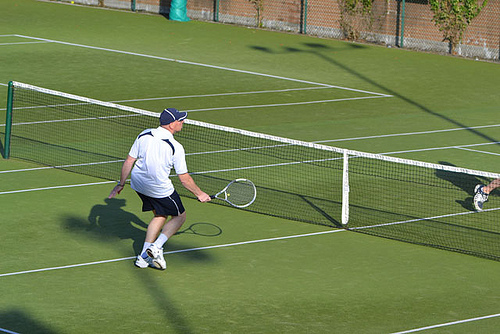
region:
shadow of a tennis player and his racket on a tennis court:
[87, 196, 222, 265]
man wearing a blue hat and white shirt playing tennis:
[106, 107, 213, 269]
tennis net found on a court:
[4, 78, 499, 258]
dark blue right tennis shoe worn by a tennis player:
[473, 183, 488, 211]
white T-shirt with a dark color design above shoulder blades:
[128, 125, 188, 198]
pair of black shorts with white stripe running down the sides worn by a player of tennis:
[136, 189, 186, 216]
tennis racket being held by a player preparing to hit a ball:
[208, 175, 256, 207]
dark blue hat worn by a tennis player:
[160, 106, 186, 128]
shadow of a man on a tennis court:
[89, 196, 150, 256]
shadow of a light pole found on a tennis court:
[249, 43, 499, 146]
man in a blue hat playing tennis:
[5, 6, 497, 326]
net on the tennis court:
[0, 77, 115, 177]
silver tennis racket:
[210, 170, 255, 210]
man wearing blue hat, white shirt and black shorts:
[106, 105, 258, 269]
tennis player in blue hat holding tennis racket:
[106, 92, 255, 269]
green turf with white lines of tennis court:
[254, 52, 467, 123]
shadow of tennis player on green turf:
[80, 197, 140, 249]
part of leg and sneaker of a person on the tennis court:
[467, 169, 497, 221]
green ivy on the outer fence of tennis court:
[419, 2, 487, 54]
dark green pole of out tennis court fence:
[390, 0, 410, 48]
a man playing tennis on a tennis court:
[109, 107, 256, 271]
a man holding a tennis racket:
[198, 175, 257, 207]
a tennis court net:
[4, 80, 499, 267]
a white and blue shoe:
[473, 183, 490, 215]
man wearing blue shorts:
[136, 188, 183, 215]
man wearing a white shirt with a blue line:
[130, 124, 188, 196]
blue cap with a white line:
[158, 107, 188, 124]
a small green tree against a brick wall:
[430, 1, 487, 54]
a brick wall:
[64, 2, 499, 61]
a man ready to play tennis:
[106, 108, 258, 268]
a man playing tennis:
[105, 91, 285, 269]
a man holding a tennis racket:
[124, 109, 289, 229]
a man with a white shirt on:
[117, 101, 223, 198]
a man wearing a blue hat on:
[127, 87, 219, 144]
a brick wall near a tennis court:
[346, 5, 478, 76]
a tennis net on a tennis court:
[280, 115, 495, 265]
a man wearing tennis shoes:
[125, 170, 220, 270]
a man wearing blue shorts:
[101, 150, 206, 227]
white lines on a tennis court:
[65, 15, 395, 115]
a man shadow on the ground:
[67, 165, 208, 270]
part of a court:
[335, 287, 345, 296]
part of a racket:
[221, 188, 231, 210]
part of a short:
[150, 192, 158, 213]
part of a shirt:
[153, 156, 163, 169]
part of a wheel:
[206, 196, 225, 199]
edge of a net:
[286, 175, 296, 200]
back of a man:
[146, 173, 152, 208]